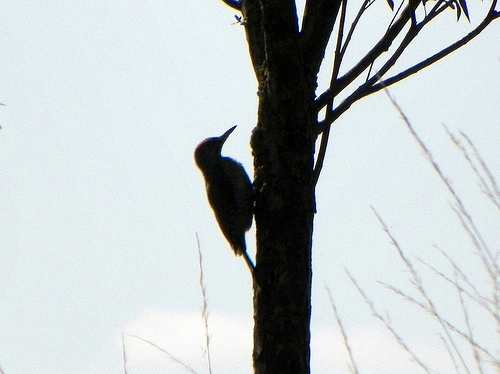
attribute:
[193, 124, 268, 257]
bird — black, standing, perched, little, stting, small, beak, outdoors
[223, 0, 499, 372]
tree — growing, leafless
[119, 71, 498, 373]
grass — growing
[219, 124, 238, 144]
beak — pointy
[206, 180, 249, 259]
wings — black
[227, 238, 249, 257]
tail — featherely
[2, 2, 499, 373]
sky — blue, bright blue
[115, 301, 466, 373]
clouds — white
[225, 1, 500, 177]
branches — bare, almost bare, small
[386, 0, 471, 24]
leaves — little, few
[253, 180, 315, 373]
trunk — small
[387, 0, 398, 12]
leaf — small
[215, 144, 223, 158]
eye — small